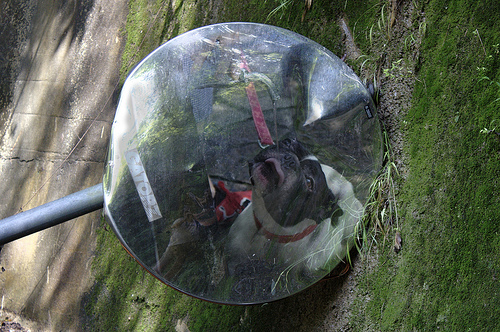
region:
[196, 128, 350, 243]
this is a dog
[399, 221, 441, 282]
this is a patch of grass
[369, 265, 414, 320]
this is a patch of grass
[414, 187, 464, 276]
this is a patch of grass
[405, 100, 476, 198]
this is a patch of grass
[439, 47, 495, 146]
this is a patch of grass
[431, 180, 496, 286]
this is a patch of grass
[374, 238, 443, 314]
this is a patch of grass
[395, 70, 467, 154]
this is a patch of grass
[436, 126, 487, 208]
this is a patch of grass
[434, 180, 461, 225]
part of a ground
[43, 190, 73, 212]
part of a handle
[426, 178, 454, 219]
par tf a ground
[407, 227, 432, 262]
part of a grund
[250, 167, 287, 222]
part of a glass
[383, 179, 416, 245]
part of a ground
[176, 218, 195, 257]
aprt of a glass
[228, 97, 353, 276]
a reflection of a dog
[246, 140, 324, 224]
dog's face is black